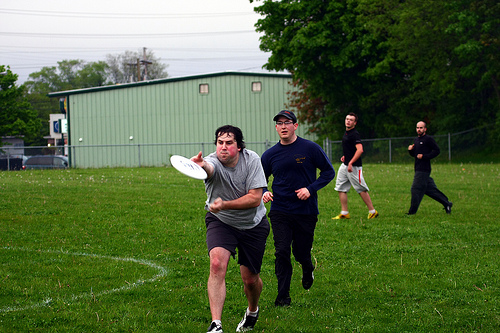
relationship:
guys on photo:
[406, 121, 453, 216] [6, 10, 498, 330]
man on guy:
[331, 111, 378, 221] [189, 125, 270, 333]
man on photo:
[260, 109, 336, 306] [6, 10, 498, 330]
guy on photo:
[189, 125, 270, 333] [6, 10, 498, 330]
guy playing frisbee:
[189, 125, 270, 333] [169, 154, 209, 180]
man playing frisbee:
[260, 109, 336, 306] [169, 154, 209, 180]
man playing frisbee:
[331, 111, 378, 221] [169, 154, 209, 180]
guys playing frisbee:
[406, 121, 453, 216] [169, 154, 209, 180]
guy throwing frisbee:
[189, 125, 270, 331] [169, 154, 209, 180]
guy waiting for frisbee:
[189, 125, 270, 333] [160, 149, 212, 191]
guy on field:
[189, 125, 270, 333] [26, 170, 498, 321]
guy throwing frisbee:
[189, 125, 270, 333] [161, 148, 213, 185]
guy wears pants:
[189, 125, 270, 333] [192, 203, 252, 283]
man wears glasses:
[259, 109, 336, 306] [268, 115, 294, 130]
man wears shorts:
[331, 111, 378, 221] [333, 159, 369, 192]